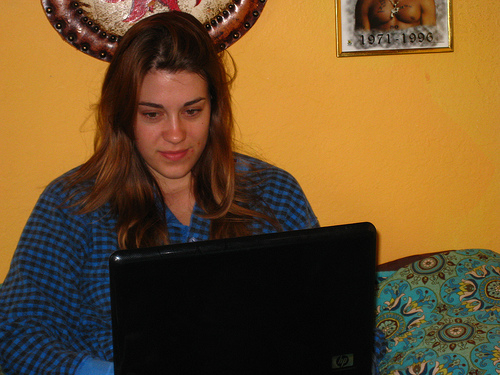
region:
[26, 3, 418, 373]
a woman using a laptop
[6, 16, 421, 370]
a brunette using a computer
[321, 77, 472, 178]
the yellow wall behind the woman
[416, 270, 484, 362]
paisley print blanket on the bed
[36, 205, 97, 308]
blue and black plaid shirt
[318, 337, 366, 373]
logo on th laptop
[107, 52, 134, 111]
brown hair on a head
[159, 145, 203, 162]
rosy pink lips on a face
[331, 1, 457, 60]
a poster on the wall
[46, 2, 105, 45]
a round wooden frame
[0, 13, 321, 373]
woman with brown hair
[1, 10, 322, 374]
woman wearing blue shirt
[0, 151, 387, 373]
shirt is blue and black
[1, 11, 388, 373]
woman looking at laptop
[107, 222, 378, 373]
HP laptop is black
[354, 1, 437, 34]
man's bare chest in picture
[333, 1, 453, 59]
memorial picture on wall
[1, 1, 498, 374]
wall is golden yellow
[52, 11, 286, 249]
straight hair is long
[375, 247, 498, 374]
bedspread is blue, green and brown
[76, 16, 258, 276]
a girl with long hair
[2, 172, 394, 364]
a black laptop computer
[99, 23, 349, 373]
a girl with a laptop on her lap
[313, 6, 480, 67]
a picture in a gold frame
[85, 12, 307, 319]
a girl looking at a computer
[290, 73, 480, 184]
a wall painted yellow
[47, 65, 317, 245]
a girl wearing a blue and black shirt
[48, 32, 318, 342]
a girl holding a laptop computer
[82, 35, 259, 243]
a girl with brown hair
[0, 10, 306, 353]
a girl sitting down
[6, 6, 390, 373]
young woman working on a laptop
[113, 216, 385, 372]
black laptop computer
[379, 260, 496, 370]
paisley and floral upholstery pattern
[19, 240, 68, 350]
blue checked fabric pattern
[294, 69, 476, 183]
orange painted wall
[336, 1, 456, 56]
picture showing a man's bare chest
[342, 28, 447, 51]
the dates 1971-1990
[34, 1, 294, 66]
lower half of an oval-shaped picture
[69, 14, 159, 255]
woman's long brown hair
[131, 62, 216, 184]
face of a young woman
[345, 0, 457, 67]
Picture of man on wall.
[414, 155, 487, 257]
Orange painted wall.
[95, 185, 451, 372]
HP black laptop.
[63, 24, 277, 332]
Woman using computer.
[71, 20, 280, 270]
Woman has long brown hair.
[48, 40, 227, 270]
Woman wearing blue and black checkered shirt.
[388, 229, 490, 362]
Aqua, brown, red, yellow flowered and circle cover.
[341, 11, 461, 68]
Birth and death date on picture.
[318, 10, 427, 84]
Gold frame on picture.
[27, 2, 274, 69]
Circular decor on wall.